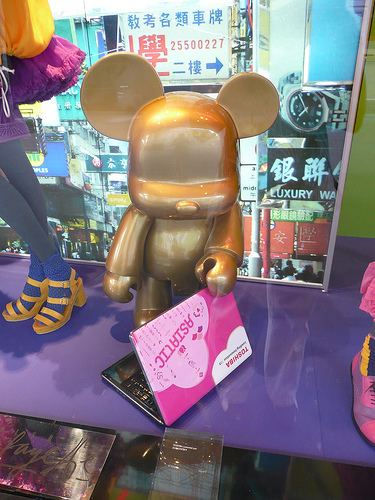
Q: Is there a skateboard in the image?
A: No, there are no skateboards.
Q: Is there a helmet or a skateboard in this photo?
A: No, there are no skateboards or helmets.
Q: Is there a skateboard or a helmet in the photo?
A: No, there are no skateboards or helmets.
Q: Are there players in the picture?
A: No, there are no players.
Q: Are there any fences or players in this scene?
A: No, there are no players or fences.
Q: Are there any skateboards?
A: No, there are no skateboards.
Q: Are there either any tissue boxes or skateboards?
A: No, there are no skateboards or tissue boxes.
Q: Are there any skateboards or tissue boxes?
A: No, there are no skateboards or tissue boxes.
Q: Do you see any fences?
A: No, there are no fences.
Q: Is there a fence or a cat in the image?
A: No, there are no fences or cats.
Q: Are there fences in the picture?
A: No, there are no fences.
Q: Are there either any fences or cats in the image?
A: No, there are no fences or cats.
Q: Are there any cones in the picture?
A: No, there are no cones.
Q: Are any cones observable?
A: No, there are no cones.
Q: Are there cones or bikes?
A: No, there are no cones or bikes.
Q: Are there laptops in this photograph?
A: Yes, there is a laptop.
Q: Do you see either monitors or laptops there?
A: Yes, there is a laptop.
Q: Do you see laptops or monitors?
A: Yes, there is a laptop.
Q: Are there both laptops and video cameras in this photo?
A: No, there is a laptop but no video cameras.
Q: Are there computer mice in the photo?
A: No, there are no computer mice.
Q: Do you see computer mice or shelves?
A: No, there are no computer mice or shelves.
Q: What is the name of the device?
A: The device is a laptop.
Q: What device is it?
A: The device is a laptop.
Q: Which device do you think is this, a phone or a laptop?
A: This is a laptop.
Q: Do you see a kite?
A: No, there are no kites.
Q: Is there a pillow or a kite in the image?
A: No, there are no kites or pillows.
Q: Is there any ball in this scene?
A: No, there are no balls.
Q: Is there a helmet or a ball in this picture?
A: No, there are no balls or helmets.